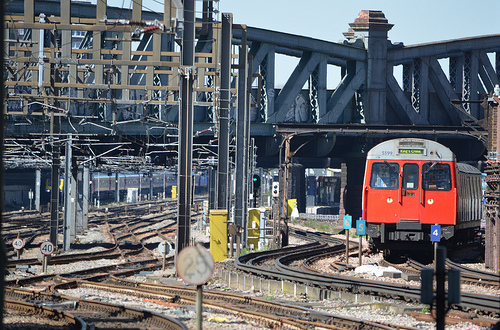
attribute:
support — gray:
[178, 0, 195, 251]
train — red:
[362, 136, 484, 256]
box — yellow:
[208, 210, 230, 260]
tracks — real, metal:
[233, 220, 499, 320]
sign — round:
[175, 242, 216, 285]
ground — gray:
[2, 286, 499, 329]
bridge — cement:
[0, 1, 499, 137]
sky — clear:
[82, 1, 500, 38]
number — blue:
[431, 226, 441, 242]